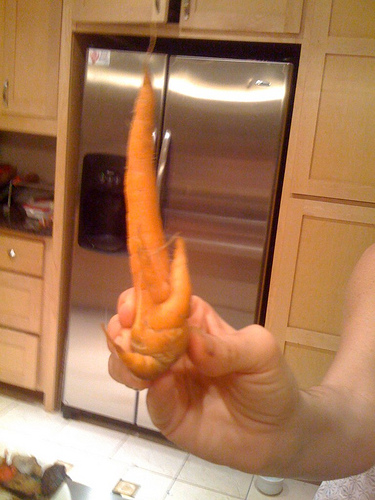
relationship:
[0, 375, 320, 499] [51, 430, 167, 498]
tile on floor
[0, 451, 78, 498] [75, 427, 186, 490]
grout on floor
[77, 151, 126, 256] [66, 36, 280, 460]
dispenser of fridge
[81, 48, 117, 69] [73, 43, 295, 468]
tag on fridge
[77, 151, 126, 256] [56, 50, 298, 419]
dispenser on a refrigerator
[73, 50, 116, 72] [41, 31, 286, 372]
magnet on refrigerator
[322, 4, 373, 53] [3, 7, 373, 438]
wooden cabinet in kitchen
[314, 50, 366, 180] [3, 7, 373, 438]
wooden cabinet in kitchen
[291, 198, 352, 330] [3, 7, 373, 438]
wooden cabinet in kitchen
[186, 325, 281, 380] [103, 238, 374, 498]
thumb of person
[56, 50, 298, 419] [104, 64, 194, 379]
refrigerator at back of carrot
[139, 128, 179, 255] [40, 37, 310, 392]
handles of a refrigerator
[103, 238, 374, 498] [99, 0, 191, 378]
person holding carrot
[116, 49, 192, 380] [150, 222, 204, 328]
carrots has bifurcations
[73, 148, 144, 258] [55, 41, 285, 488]
dispenser of refrigerator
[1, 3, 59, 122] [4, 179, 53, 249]
cabinets on top a counter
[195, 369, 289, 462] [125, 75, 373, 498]
palm of a person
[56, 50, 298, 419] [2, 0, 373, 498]
refrigerator in a kitchen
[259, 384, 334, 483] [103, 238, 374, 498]
wrist of a person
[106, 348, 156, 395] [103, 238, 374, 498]
pinky of a person